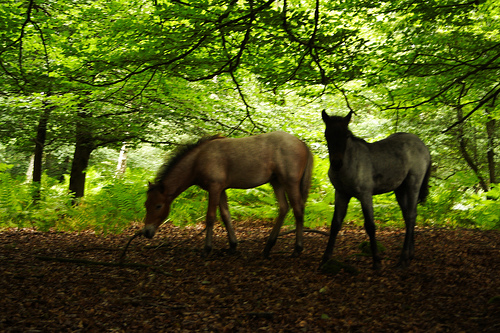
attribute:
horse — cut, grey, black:
[295, 103, 433, 263]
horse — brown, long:
[81, 102, 318, 288]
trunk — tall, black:
[64, 115, 101, 207]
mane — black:
[146, 130, 224, 194]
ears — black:
[319, 107, 354, 120]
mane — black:
[150, 140, 202, 186]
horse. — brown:
[103, 79, 323, 281]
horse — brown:
[118, 118, 495, 153]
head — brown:
[139, 174, 176, 239]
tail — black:
[423, 160, 434, 206]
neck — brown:
[156, 144, 201, 209]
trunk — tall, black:
[485, 93, 497, 187]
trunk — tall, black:
[25, 91, 63, 209]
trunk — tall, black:
[456, 77, 485, 195]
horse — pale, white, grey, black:
[311, 100, 438, 274]